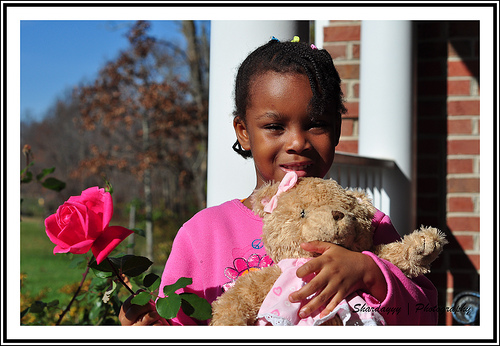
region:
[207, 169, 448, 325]
the teddy bear in the girl's arm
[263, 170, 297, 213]
the pink bow on the teddy bear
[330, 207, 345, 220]
the nose on the teddy bear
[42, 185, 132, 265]
the rose near the girl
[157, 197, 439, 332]
the pink shirt on the girl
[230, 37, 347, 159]
the hair on the girl's head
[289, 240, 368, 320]
the fingers on the girl's hand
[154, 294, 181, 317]
the green leaf on the stem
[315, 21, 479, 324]
the bricks on the building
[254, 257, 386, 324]
the clothes on the bear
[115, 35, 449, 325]
the young girl holding the bear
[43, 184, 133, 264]
the flower next to the girl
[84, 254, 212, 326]
the leaves next to the girl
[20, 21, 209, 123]
the clear blue sky above the trees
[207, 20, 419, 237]
the white part of the building behind the girl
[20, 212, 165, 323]
the green grass on the ground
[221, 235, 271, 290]
the designs on the little girls shirt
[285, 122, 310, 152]
the nose on the little girl's face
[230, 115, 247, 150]
the ear on the girl's head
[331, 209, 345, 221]
the nose on the bear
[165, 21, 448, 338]
a girl holding a teddy bear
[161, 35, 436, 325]
a girl holding a brown teddy bear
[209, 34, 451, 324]
a black girl holding a teddy bear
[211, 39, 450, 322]
an African-American girl holding a teddy bear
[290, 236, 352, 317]
the hand of a girl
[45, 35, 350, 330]
a girl holding a rose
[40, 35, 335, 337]
a girl holding a pink rose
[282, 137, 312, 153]
the nose of a girl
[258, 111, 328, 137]
the eyes of a girl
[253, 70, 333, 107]
the forehead of a girl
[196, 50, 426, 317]
this is a girl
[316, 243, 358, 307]
the girl is light skinned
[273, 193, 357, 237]
this is a doll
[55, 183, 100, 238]
this is a flower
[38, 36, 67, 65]
this is the sky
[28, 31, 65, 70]
the sky is blue in color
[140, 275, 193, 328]
these are the leaves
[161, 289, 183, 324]
the leaf is green in color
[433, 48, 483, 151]
this is the wall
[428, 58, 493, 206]
the wall is brown in color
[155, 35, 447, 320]
girl holding teddy bear to chest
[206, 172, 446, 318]
hand in front of brown bear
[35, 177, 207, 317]
blooming rose on top of green leaves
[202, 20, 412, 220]
two white columns behind girl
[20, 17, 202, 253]
deep blue sky behind trees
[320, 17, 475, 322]
brick wall behind column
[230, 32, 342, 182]
smiling face in sunlight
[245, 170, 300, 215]
pink bow at base of ear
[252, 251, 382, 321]
pink hearts on pink fabric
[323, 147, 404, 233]
ridged structure behind girl